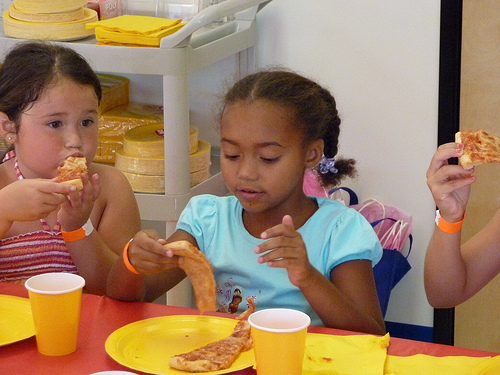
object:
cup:
[24, 272, 84, 357]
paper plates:
[114, 122, 210, 195]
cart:
[1, 0, 270, 310]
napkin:
[298, 331, 499, 375]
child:
[0, 40, 142, 295]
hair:
[0, 40, 103, 136]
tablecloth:
[0, 281, 499, 375]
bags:
[324, 185, 412, 321]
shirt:
[175, 193, 385, 329]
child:
[106, 70, 386, 334]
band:
[436, 210, 465, 233]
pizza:
[169, 297, 256, 371]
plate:
[105, 314, 255, 375]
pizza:
[53, 156, 88, 192]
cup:
[246, 306, 310, 375]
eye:
[259, 155, 280, 161]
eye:
[224, 153, 240, 159]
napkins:
[87, 14, 177, 45]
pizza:
[161, 240, 218, 315]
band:
[59, 218, 94, 240]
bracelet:
[123, 238, 140, 275]